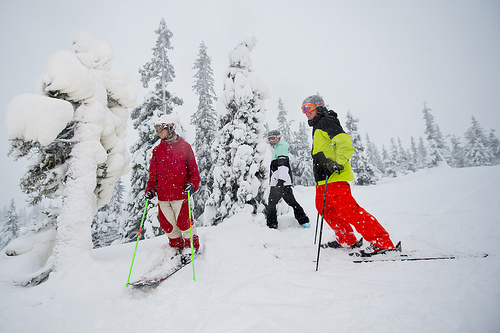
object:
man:
[267, 130, 310, 228]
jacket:
[269, 139, 293, 187]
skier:
[300, 95, 394, 258]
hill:
[0, 163, 499, 331]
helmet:
[153, 115, 178, 140]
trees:
[120, 17, 187, 244]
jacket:
[146, 133, 202, 201]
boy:
[143, 117, 201, 265]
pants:
[157, 199, 199, 247]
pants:
[315, 180, 397, 249]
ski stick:
[184, 190, 196, 281]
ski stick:
[315, 173, 330, 272]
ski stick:
[313, 212, 320, 245]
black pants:
[263, 185, 310, 229]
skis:
[135, 244, 203, 287]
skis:
[309, 248, 492, 262]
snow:
[0, 0, 499, 332]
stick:
[126, 194, 149, 288]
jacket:
[311, 109, 355, 186]